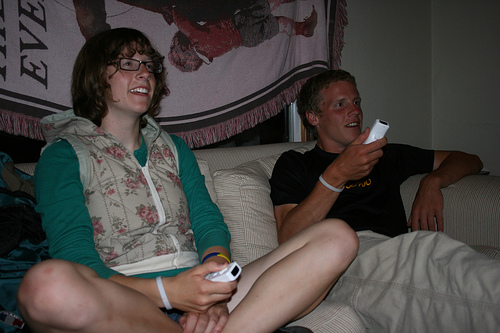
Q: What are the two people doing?
A: Playing nintendo Wii.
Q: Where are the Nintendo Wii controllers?
A: In the man's and woman's right hands.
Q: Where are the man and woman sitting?
A: On a sofa.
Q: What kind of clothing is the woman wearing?
A: She is wearing a zip up hoodie.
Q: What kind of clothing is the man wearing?
A: A black t-shirt.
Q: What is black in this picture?
A: Top man is wearing.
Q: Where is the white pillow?
A: In back of the man.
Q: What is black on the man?
A: The shirt.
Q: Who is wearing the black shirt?
A: The man.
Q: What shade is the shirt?
A: Black.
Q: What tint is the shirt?
A: Black.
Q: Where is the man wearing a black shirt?
A: On the bed.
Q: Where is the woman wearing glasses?
A: On the bed next to the man.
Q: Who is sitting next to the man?
A: A woman wearing eyeglasses.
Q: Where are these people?
A: Living room.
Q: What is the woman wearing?
A: Eyeglasses.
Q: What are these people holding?
A: Wii controllers.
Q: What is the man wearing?
A: Black t-shirt.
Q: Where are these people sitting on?
A: Couch.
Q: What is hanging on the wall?
A: Rug.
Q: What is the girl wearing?
A: A vest.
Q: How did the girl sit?
A: Crossed the legs.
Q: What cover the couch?
A: Cream fabric.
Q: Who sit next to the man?
A: A girl with glasses.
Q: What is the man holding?
A: A wii remote.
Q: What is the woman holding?
A: A wii remote.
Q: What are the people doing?
A: Playing video games.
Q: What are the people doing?
A: Playing nintendo wii.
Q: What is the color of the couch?
A: White.